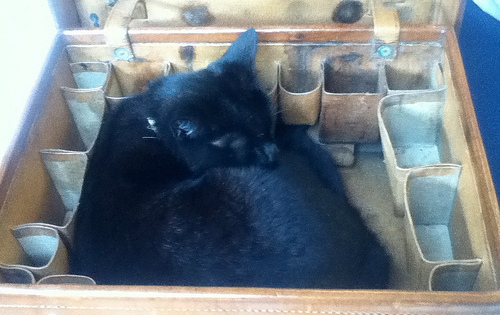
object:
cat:
[68, 25, 397, 290]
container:
[0, 24, 499, 314]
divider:
[321, 55, 387, 142]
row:
[374, 45, 498, 294]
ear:
[210, 26, 260, 86]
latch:
[369, 0, 402, 61]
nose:
[254, 134, 283, 170]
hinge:
[99, 0, 149, 68]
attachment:
[109, 47, 134, 64]